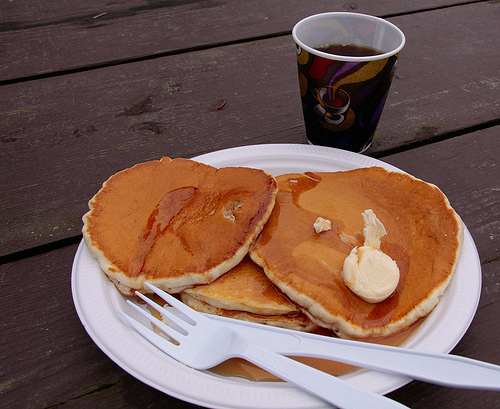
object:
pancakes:
[81, 157, 279, 289]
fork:
[117, 280, 409, 409]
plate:
[71, 142, 482, 409]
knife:
[156, 305, 499, 390]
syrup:
[124, 186, 198, 274]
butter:
[311, 209, 401, 305]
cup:
[291, 11, 405, 155]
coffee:
[294, 43, 399, 154]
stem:
[216, 98, 229, 109]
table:
[0, 1, 499, 408]